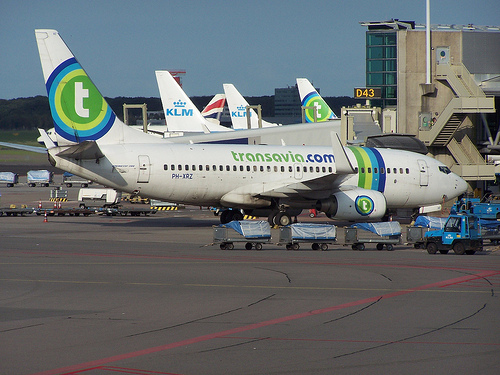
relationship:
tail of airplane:
[27, 20, 122, 137] [36, 14, 476, 235]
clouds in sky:
[84, 26, 177, 93] [0, 4, 500, 98]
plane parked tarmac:
[27, 23, 474, 233] [1, 208, 498, 373]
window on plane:
[155, 158, 167, 170] [27, 23, 474, 233]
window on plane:
[146, 146, 210, 181] [11, 46, 441, 254]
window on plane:
[212, 162, 217, 174] [35, 24, 475, 259]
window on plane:
[143, 146, 360, 187] [27, 23, 474, 233]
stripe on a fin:
[201, 95, 226, 113] [194, 91, 228, 132]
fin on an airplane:
[194, 91, 228, 132] [34, 26, 474, 259]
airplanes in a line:
[3, 22, 483, 229] [33, 31, 471, 253]